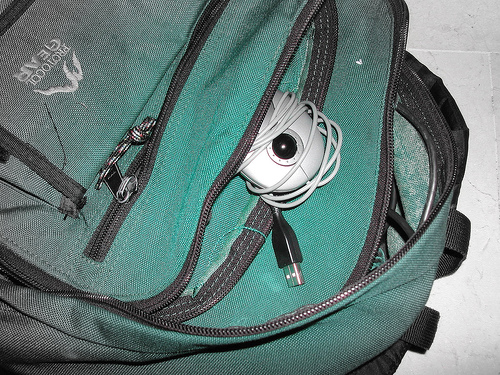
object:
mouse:
[240, 87, 343, 288]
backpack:
[0, 0, 469, 374]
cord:
[240, 89, 343, 288]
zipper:
[83, 113, 170, 261]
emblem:
[12, 37, 84, 95]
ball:
[272, 132, 297, 159]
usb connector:
[272, 207, 305, 288]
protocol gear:
[12, 37, 84, 96]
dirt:
[393, 110, 431, 232]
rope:
[94, 116, 156, 190]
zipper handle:
[103, 163, 143, 203]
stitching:
[200, 196, 274, 291]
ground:
[408, 4, 500, 375]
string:
[207, 226, 268, 268]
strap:
[435, 209, 471, 280]